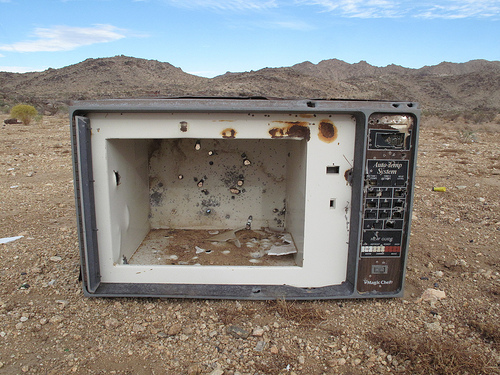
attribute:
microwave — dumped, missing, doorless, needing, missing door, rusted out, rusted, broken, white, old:
[69, 92, 425, 305]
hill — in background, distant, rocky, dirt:
[1, 54, 499, 128]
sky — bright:
[1, 2, 499, 76]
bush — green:
[6, 97, 44, 121]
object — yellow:
[426, 178, 452, 200]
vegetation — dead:
[265, 298, 499, 374]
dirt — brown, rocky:
[0, 114, 500, 374]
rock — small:
[102, 309, 124, 335]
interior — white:
[105, 134, 311, 270]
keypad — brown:
[362, 158, 408, 246]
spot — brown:
[285, 111, 313, 147]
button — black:
[379, 193, 394, 210]